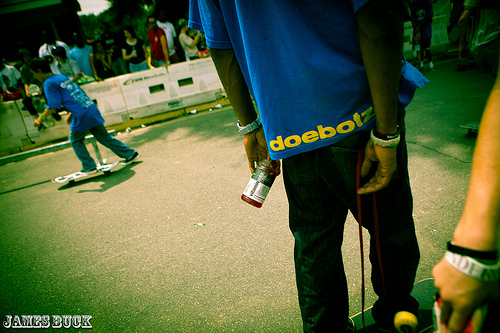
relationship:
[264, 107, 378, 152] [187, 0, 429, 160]
lettering on blue shirt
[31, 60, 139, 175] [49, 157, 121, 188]
boy on skateboard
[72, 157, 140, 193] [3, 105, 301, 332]
shadow on pavement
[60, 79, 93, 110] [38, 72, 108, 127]
lettering on shirt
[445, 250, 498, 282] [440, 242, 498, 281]
lettering on wristband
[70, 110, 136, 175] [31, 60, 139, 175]
jeans of boy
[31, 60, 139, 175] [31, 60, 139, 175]
boy watching boy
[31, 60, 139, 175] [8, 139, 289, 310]
boy skateboarding cement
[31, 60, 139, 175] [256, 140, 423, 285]
boy wearing jeans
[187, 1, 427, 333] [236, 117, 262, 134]
boy wearing bracelet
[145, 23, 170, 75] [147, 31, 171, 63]
man wearing shirt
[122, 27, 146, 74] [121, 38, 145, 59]
woman wearing shirt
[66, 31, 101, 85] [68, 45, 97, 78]
man wearing shirt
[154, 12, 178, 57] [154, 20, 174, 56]
man wearing shirt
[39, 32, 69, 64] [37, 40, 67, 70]
man wearing shirt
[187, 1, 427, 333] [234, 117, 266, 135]
boy wears bracelet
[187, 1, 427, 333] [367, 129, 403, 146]
boy wears bracelet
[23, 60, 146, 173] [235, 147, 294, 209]
boy holds bottle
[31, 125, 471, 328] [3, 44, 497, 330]
sunlight patch on pavement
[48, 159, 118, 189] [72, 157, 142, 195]
skateboard casting shadow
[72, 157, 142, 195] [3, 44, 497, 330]
shadow cast on pavement